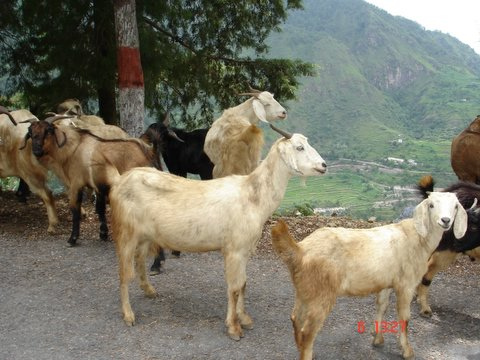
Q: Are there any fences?
A: No, there are no fences.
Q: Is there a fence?
A: No, there are no fences.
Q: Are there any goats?
A: Yes, there is a goat.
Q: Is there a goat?
A: Yes, there is a goat.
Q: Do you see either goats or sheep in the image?
A: Yes, there is a goat.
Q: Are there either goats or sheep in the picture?
A: Yes, there is a goat.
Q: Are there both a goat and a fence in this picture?
A: No, there is a goat but no fences.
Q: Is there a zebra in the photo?
A: No, there are no zebras.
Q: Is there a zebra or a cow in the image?
A: No, there are no zebras or cows.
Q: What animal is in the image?
A: The animal is a goat.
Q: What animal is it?
A: The animal is a goat.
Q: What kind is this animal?
A: This is a goat.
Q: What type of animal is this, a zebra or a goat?
A: This is a goat.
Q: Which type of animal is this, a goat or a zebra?
A: This is a goat.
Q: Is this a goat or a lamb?
A: This is a goat.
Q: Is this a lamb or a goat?
A: This is a goat.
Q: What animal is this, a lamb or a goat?
A: This is a goat.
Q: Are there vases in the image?
A: No, there are no vases.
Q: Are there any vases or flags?
A: No, there are no vases or flags.